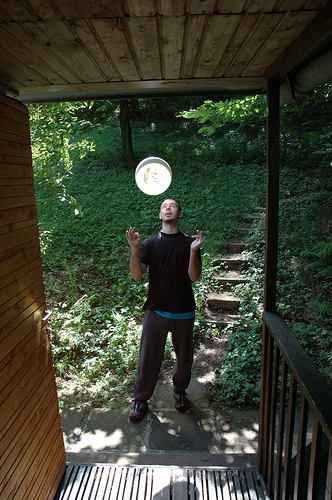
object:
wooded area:
[27, 99, 332, 407]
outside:
[25, 83, 332, 406]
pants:
[134, 310, 193, 400]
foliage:
[91, 194, 111, 228]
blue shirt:
[154, 311, 195, 319]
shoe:
[129, 401, 147, 421]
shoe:
[173, 388, 189, 411]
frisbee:
[135, 156, 173, 195]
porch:
[54, 408, 332, 500]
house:
[0, 0, 332, 500]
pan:
[135, 157, 173, 196]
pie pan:
[135, 156, 173, 196]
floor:
[53, 463, 272, 500]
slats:
[55, 464, 269, 500]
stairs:
[206, 201, 266, 314]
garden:
[24, 85, 332, 412]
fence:
[259, 312, 332, 500]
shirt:
[139, 231, 203, 314]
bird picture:
[144, 168, 150, 184]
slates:
[206, 206, 266, 311]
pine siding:
[0, 95, 67, 500]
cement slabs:
[60, 407, 314, 464]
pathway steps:
[190, 195, 291, 384]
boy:
[126, 199, 205, 422]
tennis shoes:
[129, 389, 189, 422]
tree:
[119, 100, 138, 170]